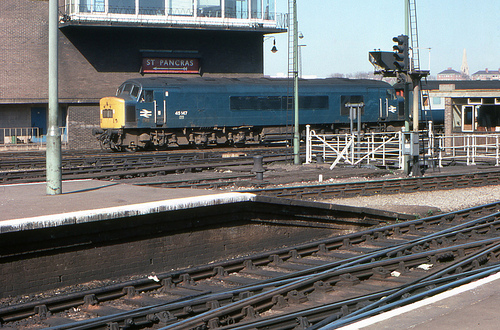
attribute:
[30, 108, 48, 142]
door — blue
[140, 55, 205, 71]
sign — white, red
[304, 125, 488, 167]
fence — white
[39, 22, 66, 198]
pole — gray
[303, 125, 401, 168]
rails — white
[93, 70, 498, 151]
train — blue